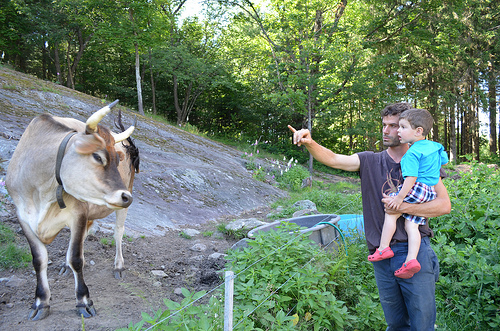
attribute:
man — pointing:
[334, 114, 400, 331]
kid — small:
[400, 111, 440, 270]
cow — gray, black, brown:
[6, 87, 157, 313]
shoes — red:
[370, 240, 445, 285]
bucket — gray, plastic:
[223, 212, 350, 262]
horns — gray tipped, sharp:
[74, 103, 145, 138]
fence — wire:
[169, 262, 295, 308]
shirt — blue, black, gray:
[398, 148, 444, 182]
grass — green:
[290, 174, 326, 194]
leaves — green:
[396, 26, 409, 36]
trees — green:
[95, 30, 242, 111]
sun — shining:
[233, 26, 277, 69]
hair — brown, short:
[410, 119, 444, 132]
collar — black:
[54, 130, 70, 193]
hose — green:
[321, 220, 354, 252]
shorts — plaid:
[412, 178, 435, 203]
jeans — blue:
[394, 281, 435, 316]